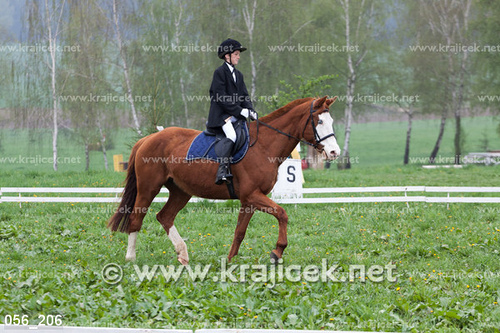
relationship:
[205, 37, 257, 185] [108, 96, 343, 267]
person riding horse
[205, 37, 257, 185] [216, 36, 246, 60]
person wearing helmet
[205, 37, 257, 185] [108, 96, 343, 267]
person on horse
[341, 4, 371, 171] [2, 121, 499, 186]
tree in field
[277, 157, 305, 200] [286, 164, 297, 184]
sign with s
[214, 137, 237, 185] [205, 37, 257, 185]
boot on person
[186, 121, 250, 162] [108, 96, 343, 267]
blanket on horse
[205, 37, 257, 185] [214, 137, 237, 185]
person wearing boot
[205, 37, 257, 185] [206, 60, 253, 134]
person wearing coat